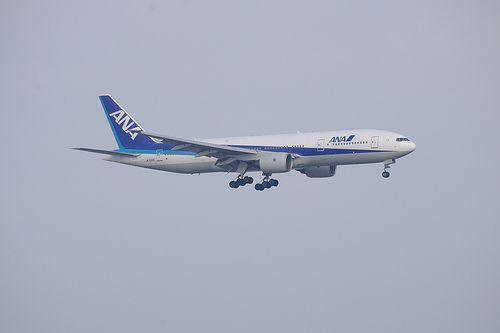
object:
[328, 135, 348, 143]
"ana"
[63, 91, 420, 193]
plane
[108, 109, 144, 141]
word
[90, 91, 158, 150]
tail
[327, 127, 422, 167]
front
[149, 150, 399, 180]
bottom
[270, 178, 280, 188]
wheel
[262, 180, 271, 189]
wheel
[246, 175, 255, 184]
wheel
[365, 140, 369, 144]
window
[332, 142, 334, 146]
window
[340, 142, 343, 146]
window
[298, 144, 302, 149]
window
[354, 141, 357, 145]
window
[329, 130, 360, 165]
part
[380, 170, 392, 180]
landing gear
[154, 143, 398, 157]
stripe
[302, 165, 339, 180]
engine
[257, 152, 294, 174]
engine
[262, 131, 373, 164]
side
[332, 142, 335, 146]
small window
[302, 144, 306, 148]
small window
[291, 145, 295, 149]
small window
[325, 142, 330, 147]
windows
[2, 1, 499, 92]
sky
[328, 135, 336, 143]
letter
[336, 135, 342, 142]
letter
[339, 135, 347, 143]
letter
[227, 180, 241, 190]
landing wheels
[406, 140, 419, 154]
nose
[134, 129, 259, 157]
wing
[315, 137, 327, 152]
door